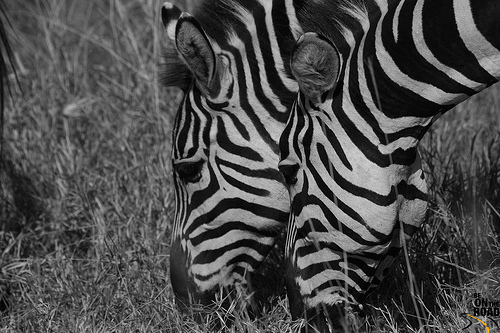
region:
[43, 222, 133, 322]
black and white grass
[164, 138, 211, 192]
a zebras left eye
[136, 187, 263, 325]
a zebras nose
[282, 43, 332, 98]
a zebras left ear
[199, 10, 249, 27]
a zebras black mane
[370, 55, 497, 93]
a zebras neck with stripes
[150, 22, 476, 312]
two zebras eating grass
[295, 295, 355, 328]
a zebras mouth eating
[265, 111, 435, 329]
a zebras whole head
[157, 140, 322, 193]
two zebras left eyes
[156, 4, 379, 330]
Two zebras grazing on grass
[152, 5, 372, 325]
Two zebras side by side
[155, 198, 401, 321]
Two hungry animal mouths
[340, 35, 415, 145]
Black and white stripes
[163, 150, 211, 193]
Black zebra eye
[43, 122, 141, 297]
Field of grass in black and white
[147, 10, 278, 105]
Zebra ears intensely listen for prey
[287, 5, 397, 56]
Fuzzy striped zebra mane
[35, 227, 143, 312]
Dry grass in the savannah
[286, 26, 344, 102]
Fuzzy soft zebra ear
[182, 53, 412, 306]
the zebra's grazing in the grass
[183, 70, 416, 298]
the colors of the zebra's are black and white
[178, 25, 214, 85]
the zebra's ear is furry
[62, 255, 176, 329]
the zebra is eating grass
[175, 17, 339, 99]
the ears are different shapes on each zebra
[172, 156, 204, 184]
the zebra has black eyes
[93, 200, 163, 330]
the grass looks rough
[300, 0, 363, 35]
the hair on top of zebra's head is black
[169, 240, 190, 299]
the nose on zebra is black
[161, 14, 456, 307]
the zebra's are eating togehter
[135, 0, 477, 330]
Two Zebras Grazing Together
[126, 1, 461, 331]
Zebras in Black and White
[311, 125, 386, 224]
Black and White Stripes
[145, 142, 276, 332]
The Face of a Zebra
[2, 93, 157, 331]
Black and White Shot of Grass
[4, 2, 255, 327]
A Zebra Eating Grass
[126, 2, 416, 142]
Ears of the Zebra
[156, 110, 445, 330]
Zebras Grazing Together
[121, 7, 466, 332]
Mother and Foal Zebras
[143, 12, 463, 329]
Zebra Herd Foraging Together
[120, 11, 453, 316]
two zebra heads in the grass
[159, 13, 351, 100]
the fuzzy ears on the zebra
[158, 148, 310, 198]
the black eyes of the zebra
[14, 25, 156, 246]
long grasses the zebras are eating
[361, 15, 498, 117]
the striped neck of the zebra on the right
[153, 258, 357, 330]
the mouths in the grass of the zebra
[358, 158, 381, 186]
a white part of the zebra's face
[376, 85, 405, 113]
a black part of the zebra's neck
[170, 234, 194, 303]
the nose of the zebra on the left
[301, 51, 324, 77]
the ear fuzz of the zebra on the right